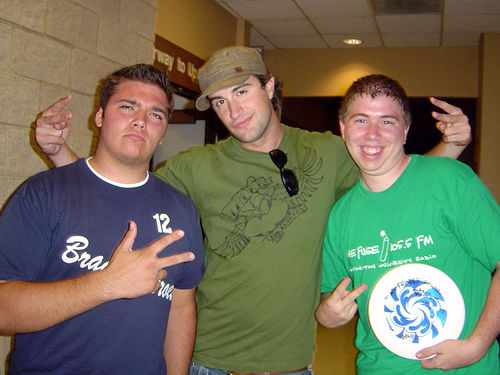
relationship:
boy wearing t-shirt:
[0, 62, 205, 374] [0, 158, 208, 373]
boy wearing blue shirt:
[33, 45, 472, 374] [0, 157, 206, 375]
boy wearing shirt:
[313, 73, 499, 374] [319, 153, 500, 374]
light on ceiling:
[342, 35, 363, 45] [231, 2, 499, 48]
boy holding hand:
[33, 45, 472, 374] [426, 94, 471, 146]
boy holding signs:
[33, 45, 472, 374] [316, 275, 368, 331]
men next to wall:
[0, 45, 497, 373] [0, 1, 156, 372]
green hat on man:
[196, 45, 267, 111] [29, 39, 466, 354]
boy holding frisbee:
[313, 73, 498, 373] [368, 260, 466, 363]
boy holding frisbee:
[313, 73, 498, 373] [370, 265, 466, 358]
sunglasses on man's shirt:
[266, 149, 302, 197] [153, 124, 364, 374]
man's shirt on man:
[153, 124, 364, 374] [168, 47, 336, 372]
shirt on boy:
[319, 153, 500, 374] [292, 60, 497, 374]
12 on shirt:
[152, 213, 173, 234] [3, 159, 211, 369]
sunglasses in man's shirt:
[268, 149, 299, 198] [153, 124, 364, 374]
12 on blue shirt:
[146, 202, 176, 238] [3, 156, 198, 373]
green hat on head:
[183, 55, 287, 122] [185, 52, 282, 149]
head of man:
[185, 52, 282, 149] [29, 39, 466, 354]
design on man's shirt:
[213, 141, 324, 265] [148, 121, 366, 371]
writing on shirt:
[56, 229, 176, 305] [59, 175, 148, 212]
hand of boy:
[121, 220, 206, 311] [0, 62, 205, 374]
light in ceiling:
[343, 38, 363, 45] [231, 2, 499, 48]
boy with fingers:
[4, 57, 209, 373] [112, 215, 197, 268]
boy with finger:
[33, 45, 478, 372] [429, 94, 459, 113]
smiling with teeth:
[345, 131, 407, 174] [357, 143, 388, 155]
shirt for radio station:
[316, 151, 498, 372] [347, 232, 436, 258]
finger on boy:
[341, 281, 366, 307] [313, 73, 498, 373]